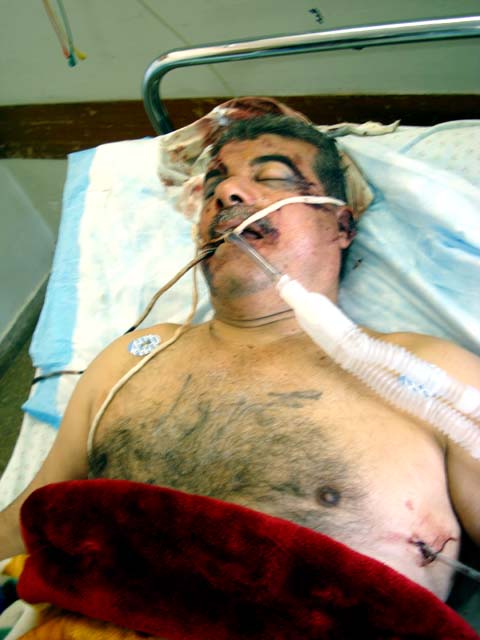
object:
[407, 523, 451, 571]
needle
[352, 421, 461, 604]
side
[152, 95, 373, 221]
cloth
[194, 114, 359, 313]
head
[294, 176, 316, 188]
cut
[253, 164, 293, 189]
eye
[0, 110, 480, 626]
man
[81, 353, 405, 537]
chest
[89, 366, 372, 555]
hair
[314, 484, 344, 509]
nipple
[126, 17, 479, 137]
railing